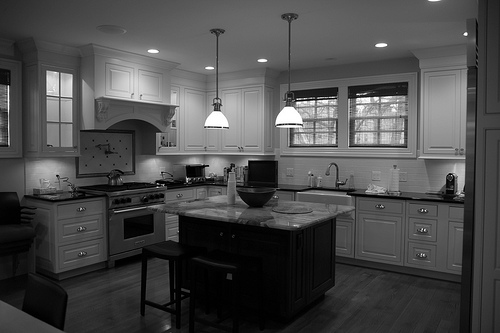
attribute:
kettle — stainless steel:
[102, 167, 125, 187]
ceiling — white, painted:
[136, 0, 193, 43]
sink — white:
[300, 159, 359, 207]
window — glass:
[347, 87, 432, 147]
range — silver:
[85, 175, 172, 257]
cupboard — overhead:
[413, 50, 469, 156]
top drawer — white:
[53, 197, 108, 215]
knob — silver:
[73, 191, 95, 226]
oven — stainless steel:
[107, 195, 175, 253]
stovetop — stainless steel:
[88, 173, 168, 195]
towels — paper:
[387, 166, 402, 196]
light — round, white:
[145, 42, 165, 59]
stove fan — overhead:
[81, 45, 180, 135]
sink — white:
[293, 185, 348, 215]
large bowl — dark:
[232, 184, 277, 209]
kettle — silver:
[104, 168, 124, 188]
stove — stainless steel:
[98, 177, 168, 258]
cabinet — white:
[25, 194, 111, 278]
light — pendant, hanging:
[271, 10, 305, 142]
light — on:
[264, 95, 308, 132]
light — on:
[198, 97, 233, 131]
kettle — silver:
[97, 160, 136, 190]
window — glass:
[285, 86, 340, 149]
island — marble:
[141, 183, 359, 328]